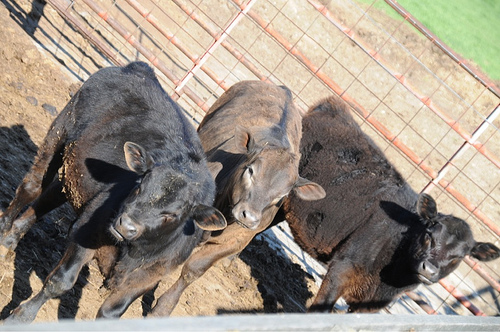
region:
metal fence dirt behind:
[383, 29, 446, 132]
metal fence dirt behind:
[268, 9, 358, 93]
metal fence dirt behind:
[130, 11, 215, 58]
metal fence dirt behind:
[26, 15, 158, 49]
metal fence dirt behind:
[428, 99, 493, 164]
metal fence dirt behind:
[336, 24, 402, 122]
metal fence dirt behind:
[426, 40, 465, 172]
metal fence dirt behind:
[272, 25, 479, 118]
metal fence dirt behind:
[151, 6, 278, 18]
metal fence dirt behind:
[388, 16, 436, 132]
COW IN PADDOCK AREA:
[8, 57, 202, 317]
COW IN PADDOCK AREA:
[191, 75, 326, 322]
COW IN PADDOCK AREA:
[305, 88, 496, 328]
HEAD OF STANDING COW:
[101, 129, 226, 248]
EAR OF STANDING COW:
[117, 140, 156, 175]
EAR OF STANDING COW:
[190, 205, 231, 240]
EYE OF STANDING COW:
[131, 178, 148, 195]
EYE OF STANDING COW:
[158, 205, 179, 220]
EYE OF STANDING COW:
[245, 162, 263, 179]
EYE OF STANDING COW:
[421, 227, 438, 246]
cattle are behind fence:
[55, 60, 464, 320]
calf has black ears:
[395, 188, 497, 251]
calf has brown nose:
[228, 205, 269, 226]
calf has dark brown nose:
[410, 248, 442, 286]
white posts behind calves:
[401, 83, 492, 213]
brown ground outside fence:
[205, 36, 430, 92]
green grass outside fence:
[410, 8, 491, 61]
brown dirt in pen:
[21, 52, 58, 135]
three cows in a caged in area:
[6, 66, 498, 309]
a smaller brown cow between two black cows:
[157, 69, 312, 319]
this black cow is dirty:
[7, 55, 215, 320]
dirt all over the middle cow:
[163, 72, 333, 307]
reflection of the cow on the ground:
[2, 123, 84, 317]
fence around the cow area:
[4, 0, 497, 322]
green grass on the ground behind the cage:
[390, 0, 497, 92]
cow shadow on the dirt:
[237, 242, 327, 314]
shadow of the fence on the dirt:
[1, 1, 121, 82]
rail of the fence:
[0, 319, 496, 328]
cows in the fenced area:
[11, 45, 498, 318]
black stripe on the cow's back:
[267, 101, 293, 148]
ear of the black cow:
[415, 188, 439, 228]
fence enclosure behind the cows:
[388, 44, 443, 119]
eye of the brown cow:
[243, 153, 260, 185]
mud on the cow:
[55, 139, 83, 214]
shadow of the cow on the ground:
[2, 118, 33, 171]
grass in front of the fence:
[434, 10, 481, 37]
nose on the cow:
[114, 215, 144, 235]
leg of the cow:
[321, 265, 344, 307]